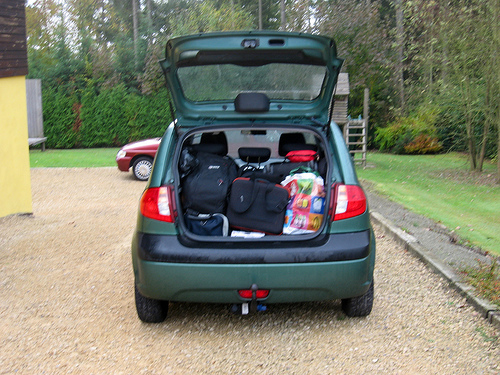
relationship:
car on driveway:
[129, 35, 379, 322] [3, 165, 498, 373]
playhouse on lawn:
[321, 61, 378, 157] [373, 144, 483, 235]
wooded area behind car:
[22, 2, 500, 156] [129, 35, 379, 322]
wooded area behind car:
[22, 2, 500, 156] [114, 136, 161, 181]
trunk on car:
[164, 38, 351, 255] [124, 21, 394, 333]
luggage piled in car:
[185, 152, 329, 236] [129, 35, 379, 322]